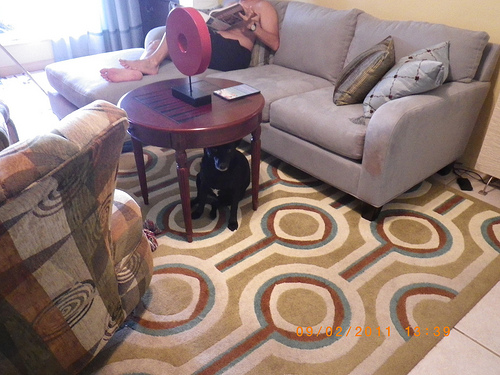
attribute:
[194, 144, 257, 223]
dog — black 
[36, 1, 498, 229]
couch — gray 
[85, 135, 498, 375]
rug — patterned